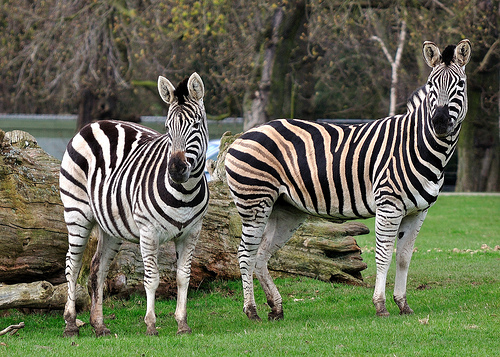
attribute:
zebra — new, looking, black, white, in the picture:
[52, 73, 210, 335]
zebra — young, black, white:
[225, 40, 473, 320]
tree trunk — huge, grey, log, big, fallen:
[2, 126, 368, 291]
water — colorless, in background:
[1, 109, 245, 169]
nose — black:
[168, 151, 189, 179]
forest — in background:
[5, 1, 499, 193]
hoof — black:
[143, 320, 157, 338]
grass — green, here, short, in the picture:
[0, 193, 499, 356]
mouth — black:
[182, 173, 191, 179]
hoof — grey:
[177, 316, 190, 334]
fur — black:
[436, 42, 450, 62]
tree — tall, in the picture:
[232, 3, 316, 125]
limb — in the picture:
[137, 229, 163, 326]